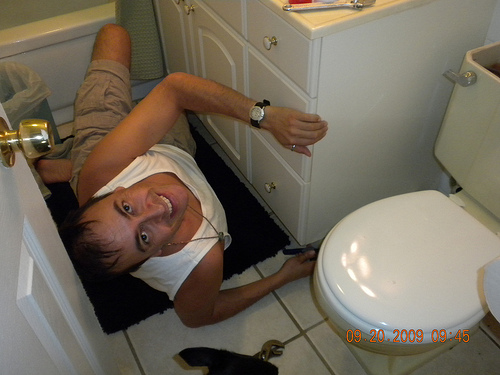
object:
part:
[263, 344, 270, 350]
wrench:
[259, 339, 284, 361]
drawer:
[245, 0, 312, 99]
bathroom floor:
[106, 251, 499, 375]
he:
[19, 20, 322, 327]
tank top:
[93, 144, 232, 301]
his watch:
[249, 99, 271, 129]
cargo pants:
[43, 59, 197, 197]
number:
[347, 329, 470, 343]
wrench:
[282, 0, 378, 11]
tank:
[433, 40, 500, 220]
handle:
[442, 69, 477, 88]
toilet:
[307, 39, 500, 356]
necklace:
[162, 204, 223, 246]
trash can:
[0, 59, 63, 145]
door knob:
[1, 117, 55, 168]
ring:
[291, 144, 296, 150]